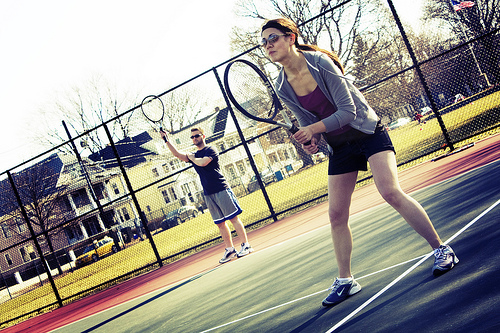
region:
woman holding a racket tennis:
[223, 17, 461, 304]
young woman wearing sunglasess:
[222, 18, 462, 305]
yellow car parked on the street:
[76, 233, 130, 265]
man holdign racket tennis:
[140, 92, 255, 263]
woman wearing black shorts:
[223, 18, 463, 304]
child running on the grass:
[411, 98, 429, 130]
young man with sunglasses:
[141, 90, 254, 265]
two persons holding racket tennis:
[138, 16, 458, 308]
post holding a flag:
[447, 0, 494, 89]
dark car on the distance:
[156, 201, 200, 229]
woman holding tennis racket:
[220, 5, 439, 265]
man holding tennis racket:
[135, 95, 261, 268]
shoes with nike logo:
[306, 248, 472, 312]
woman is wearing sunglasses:
[238, 17, 325, 97]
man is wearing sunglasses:
[170, 122, 228, 189]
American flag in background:
[437, 3, 499, 102]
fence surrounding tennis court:
[21, 73, 498, 168]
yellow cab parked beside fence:
[67, 238, 127, 265]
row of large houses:
[42, 145, 273, 239]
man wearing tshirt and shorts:
[175, 132, 246, 256]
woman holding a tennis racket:
[229, 12, 453, 303]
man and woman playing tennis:
[170, 32, 431, 292]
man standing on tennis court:
[137, 112, 260, 282]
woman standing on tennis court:
[267, 21, 451, 314]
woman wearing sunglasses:
[257, 22, 281, 63]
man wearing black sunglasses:
[187, 130, 207, 150]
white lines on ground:
[312, 252, 424, 332]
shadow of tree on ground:
[422, 169, 498, 229]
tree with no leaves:
[47, 96, 152, 153]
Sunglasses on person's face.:
[244, 22, 287, 45]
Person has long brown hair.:
[257, 16, 327, 75]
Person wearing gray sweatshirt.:
[259, 74, 391, 143]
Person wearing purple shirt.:
[297, 87, 348, 139]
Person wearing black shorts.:
[322, 124, 379, 192]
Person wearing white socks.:
[308, 262, 375, 285]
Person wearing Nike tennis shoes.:
[307, 267, 361, 327]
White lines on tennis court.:
[367, 227, 414, 329]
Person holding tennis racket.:
[236, 56, 309, 177]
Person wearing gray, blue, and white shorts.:
[203, 181, 260, 217]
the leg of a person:
[371, 155, 443, 245]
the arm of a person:
[156, 127, 183, 160]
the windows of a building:
[3, 249, 32, 264]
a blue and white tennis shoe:
[321, 281, 365, 305]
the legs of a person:
[211, 205, 251, 250]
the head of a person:
[188, 125, 210, 148]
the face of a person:
[260, 29, 282, 68]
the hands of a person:
[291, 118, 322, 159]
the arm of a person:
[316, 54, 354, 135]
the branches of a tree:
[328, 15, 362, 44]